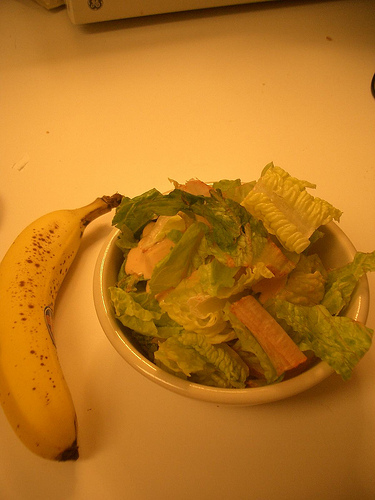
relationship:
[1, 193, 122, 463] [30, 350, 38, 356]
banana has spot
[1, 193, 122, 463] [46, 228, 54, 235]
banana has spot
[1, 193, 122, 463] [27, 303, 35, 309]
banana has spot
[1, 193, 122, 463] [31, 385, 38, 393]
banana has spot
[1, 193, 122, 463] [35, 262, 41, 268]
banana has spot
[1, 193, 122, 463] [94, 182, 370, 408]
banana next to bowl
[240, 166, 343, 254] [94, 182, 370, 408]
lettuce in bowl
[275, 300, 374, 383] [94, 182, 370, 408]
lettuce in bowl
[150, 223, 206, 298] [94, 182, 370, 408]
lettuce in bowl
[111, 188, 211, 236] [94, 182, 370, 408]
lettuce in bowl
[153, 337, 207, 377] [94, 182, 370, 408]
lettuce in bowl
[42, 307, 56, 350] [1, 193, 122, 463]
sticker on banana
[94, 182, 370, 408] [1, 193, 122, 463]
bowl next to banana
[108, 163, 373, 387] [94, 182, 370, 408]
food in bowl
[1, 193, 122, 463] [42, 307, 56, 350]
banana has sticker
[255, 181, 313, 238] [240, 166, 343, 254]
rib in lettuce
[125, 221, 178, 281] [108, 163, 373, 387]
salad dressing on food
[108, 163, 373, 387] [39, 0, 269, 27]
food near appliance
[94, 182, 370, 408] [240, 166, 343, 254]
bowl filled with lettuce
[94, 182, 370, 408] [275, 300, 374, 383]
bowl filled with lettuce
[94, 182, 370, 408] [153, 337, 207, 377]
bowl filled with lettuce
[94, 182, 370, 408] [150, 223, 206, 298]
bowl filled with lettuce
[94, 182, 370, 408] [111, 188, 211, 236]
bowl filled with lettuce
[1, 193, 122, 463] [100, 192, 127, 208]
banana has tip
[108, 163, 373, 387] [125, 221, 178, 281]
food has salad dressing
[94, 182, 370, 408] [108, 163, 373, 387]
bowl has food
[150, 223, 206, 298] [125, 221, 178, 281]
lettuce has salad dressing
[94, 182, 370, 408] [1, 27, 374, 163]
bowl on surface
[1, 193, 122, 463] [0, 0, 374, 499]
banana on surface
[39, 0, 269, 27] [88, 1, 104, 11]
appliance has logo